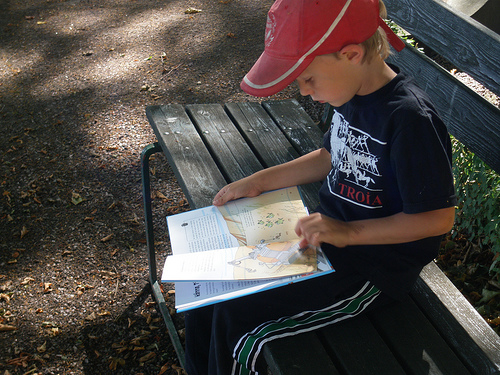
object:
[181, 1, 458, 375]
boy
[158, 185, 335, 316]
book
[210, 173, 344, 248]
hands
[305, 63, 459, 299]
shirt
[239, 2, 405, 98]
hat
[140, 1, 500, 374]
bench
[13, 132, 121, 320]
leaves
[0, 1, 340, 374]
ground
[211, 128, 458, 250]
arms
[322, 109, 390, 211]
logo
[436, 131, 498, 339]
bush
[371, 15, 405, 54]
strap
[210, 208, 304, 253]
design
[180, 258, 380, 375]
pants